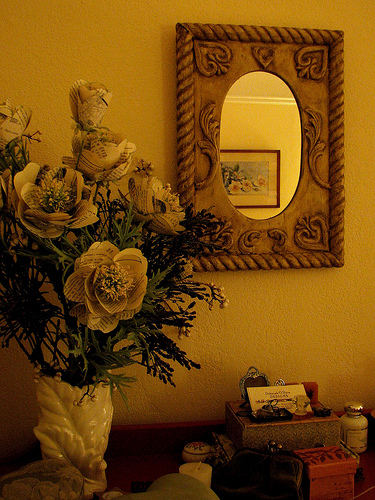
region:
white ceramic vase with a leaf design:
[42, 361, 124, 490]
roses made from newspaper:
[32, 169, 170, 358]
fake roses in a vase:
[32, 133, 172, 491]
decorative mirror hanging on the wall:
[174, 19, 359, 290]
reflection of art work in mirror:
[208, 138, 293, 215]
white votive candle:
[177, 456, 215, 488]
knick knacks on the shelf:
[185, 356, 369, 492]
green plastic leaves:
[70, 331, 142, 404]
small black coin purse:
[212, 438, 303, 497]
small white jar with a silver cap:
[335, 394, 371, 452]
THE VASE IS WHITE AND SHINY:
[30, 372, 120, 494]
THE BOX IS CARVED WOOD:
[286, 437, 361, 497]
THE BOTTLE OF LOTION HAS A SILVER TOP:
[337, 394, 370, 461]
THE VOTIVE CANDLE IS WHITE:
[176, 458, 224, 494]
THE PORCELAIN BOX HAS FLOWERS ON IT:
[178, 425, 215, 465]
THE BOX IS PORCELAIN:
[175, 431, 212, 472]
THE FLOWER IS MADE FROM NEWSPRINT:
[60, 234, 154, 339]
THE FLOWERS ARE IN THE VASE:
[0, 75, 247, 394]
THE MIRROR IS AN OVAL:
[204, 57, 310, 232]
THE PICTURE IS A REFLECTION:
[220, 145, 285, 214]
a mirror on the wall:
[167, 16, 350, 271]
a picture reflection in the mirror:
[214, 144, 285, 213]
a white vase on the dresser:
[31, 367, 109, 490]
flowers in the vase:
[6, 58, 262, 408]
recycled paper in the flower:
[62, 243, 149, 333]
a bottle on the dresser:
[336, 395, 369, 457]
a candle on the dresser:
[171, 457, 211, 485]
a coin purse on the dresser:
[212, 436, 305, 499]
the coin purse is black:
[213, 439, 304, 495]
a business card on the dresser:
[246, 382, 313, 416]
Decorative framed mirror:
[175, 21, 344, 272]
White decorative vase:
[30, 366, 117, 488]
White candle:
[181, 457, 215, 488]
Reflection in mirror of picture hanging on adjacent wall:
[220, 145, 283, 210]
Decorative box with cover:
[294, 446, 358, 497]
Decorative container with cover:
[179, 438, 209, 461]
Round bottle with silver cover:
[341, 398, 371, 455]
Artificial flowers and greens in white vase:
[0, 71, 229, 474]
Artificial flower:
[69, 237, 147, 331]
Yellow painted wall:
[0, 1, 178, 79]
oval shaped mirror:
[218, 71, 302, 220]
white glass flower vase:
[36, 376, 111, 490]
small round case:
[182, 439, 210, 464]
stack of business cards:
[246, 384, 309, 414]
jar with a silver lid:
[340, 404, 368, 452]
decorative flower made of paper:
[68, 242, 146, 332]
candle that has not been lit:
[180, 461, 211, 485]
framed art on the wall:
[215, 149, 280, 207]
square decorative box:
[301, 448, 355, 498]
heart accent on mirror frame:
[296, 217, 331, 250]